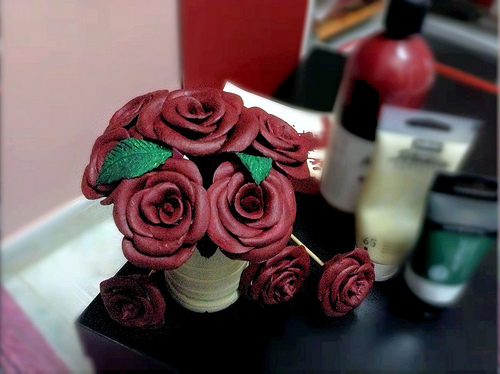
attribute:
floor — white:
[33, 255, 84, 309]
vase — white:
[176, 242, 243, 313]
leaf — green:
[98, 136, 172, 182]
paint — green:
[398, 149, 499, 326]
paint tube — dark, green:
[395, 169, 498, 331]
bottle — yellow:
[349, 150, 429, 280]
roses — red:
[82, 96, 303, 264]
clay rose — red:
[196, 147, 298, 267]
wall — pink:
[47, 51, 104, 91]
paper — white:
[205, 62, 382, 214]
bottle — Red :
[319, 2, 439, 229]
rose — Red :
[315, 246, 375, 320]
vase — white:
[162, 247, 249, 312]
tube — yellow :
[401, 165, 499, 315]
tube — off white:
[349, 105, 477, 281]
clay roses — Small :
[19, 30, 414, 350]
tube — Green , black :
[406, 177, 498, 307]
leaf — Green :
[94, 133, 176, 188]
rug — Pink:
[2, 193, 137, 372]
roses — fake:
[80, 86, 376, 328]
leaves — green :
[153, 130, 295, 202]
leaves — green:
[88, 116, 295, 204]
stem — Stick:
[280, 220, 330, 275]